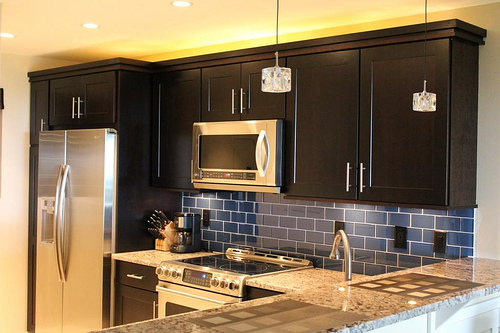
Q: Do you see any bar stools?
A: No, there are no bar stools.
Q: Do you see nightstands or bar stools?
A: No, there are no bar stools or nightstands.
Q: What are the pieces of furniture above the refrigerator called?
A: The pieces of furniture are cabinets.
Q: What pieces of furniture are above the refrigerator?
A: The pieces of furniture are cabinets.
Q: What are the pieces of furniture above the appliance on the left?
A: The pieces of furniture are cabinets.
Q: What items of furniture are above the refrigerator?
A: The pieces of furniture are cabinets.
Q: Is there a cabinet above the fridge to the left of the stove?
A: Yes, there are cabinets above the freezer.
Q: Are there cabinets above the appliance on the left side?
A: Yes, there are cabinets above the freezer.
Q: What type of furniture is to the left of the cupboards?
A: The pieces of furniture are cabinets.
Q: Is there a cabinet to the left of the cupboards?
A: Yes, there are cabinets to the left of the cupboards.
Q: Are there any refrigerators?
A: Yes, there is a refrigerator.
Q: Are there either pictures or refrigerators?
A: Yes, there is a refrigerator.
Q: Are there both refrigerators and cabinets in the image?
A: Yes, there are both a refrigerator and cabinets.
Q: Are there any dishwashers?
A: No, there are no dishwashers.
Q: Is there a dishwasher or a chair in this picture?
A: No, there are no dishwashers or chairs.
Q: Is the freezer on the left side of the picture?
A: Yes, the freezer is on the left of the image.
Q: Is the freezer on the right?
A: No, the freezer is on the left of the image.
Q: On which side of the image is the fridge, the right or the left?
A: The fridge is on the left of the image.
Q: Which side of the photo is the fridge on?
A: The fridge is on the left of the image.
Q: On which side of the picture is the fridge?
A: The fridge is on the left of the image.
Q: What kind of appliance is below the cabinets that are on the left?
A: The appliance is a refrigerator.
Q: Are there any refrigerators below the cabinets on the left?
A: Yes, there is a refrigerator below the cabinets.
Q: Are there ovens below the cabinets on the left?
A: No, there is a refrigerator below the cabinets.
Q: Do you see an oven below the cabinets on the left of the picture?
A: No, there is a refrigerator below the cabinets.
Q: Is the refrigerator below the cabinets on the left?
A: Yes, the refrigerator is below the cabinets.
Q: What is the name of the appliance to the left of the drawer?
A: The appliance is a refrigerator.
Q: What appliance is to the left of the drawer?
A: The appliance is a refrigerator.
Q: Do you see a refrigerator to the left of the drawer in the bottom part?
A: Yes, there is a refrigerator to the left of the drawer.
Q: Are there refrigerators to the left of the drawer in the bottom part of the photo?
A: Yes, there is a refrigerator to the left of the drawer.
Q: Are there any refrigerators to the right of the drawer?
A: No, the refrigerator is to the left of the drawer.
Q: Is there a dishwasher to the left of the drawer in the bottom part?
A: No, there is a refrigerator to the left of the drawer.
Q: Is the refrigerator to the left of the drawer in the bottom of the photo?
A: Yes, the refrigerator is to the left of the drawer.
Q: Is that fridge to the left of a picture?
A: No, the fridge is to the left of the drawer.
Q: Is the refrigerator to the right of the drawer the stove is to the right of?
A: No, the refrigerator is to the left of the drawer.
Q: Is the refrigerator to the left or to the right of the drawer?
A: The refrigerator is to the left of the drawer.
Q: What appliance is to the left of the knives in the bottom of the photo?
A: The appliance is a refrigerator.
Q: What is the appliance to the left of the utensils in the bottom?
A: The appliance is a refrigerator.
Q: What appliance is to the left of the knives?
A: The appliance is a refrigerator.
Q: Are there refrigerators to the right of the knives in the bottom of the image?
A: No, the refrigerator is to the left of the knives.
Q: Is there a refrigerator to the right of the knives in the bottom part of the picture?
A: No, the refrigerator is to the left of the knives.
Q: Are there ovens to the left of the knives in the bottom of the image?
A: No, there is a refrigerator to the left of the knives.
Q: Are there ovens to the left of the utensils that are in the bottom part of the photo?
A: No, there is a refrigerator to the left of the knives.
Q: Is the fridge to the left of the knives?
A: Yes, the fridge is to the left of the knives.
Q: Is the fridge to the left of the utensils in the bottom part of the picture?
A: Yes, the fridge is to the left of the knives.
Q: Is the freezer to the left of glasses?
A: No, the freezer is to the left of the knives.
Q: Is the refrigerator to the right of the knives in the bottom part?
A: No, the refrigerator is to the left of the knives.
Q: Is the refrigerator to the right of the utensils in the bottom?
A: No, the refrigerator is to the left of the knives.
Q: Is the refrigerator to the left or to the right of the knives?
A: The refrigerator is to the left of the knives.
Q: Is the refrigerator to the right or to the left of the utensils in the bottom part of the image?
A: The refrigerator is to the left of the knives.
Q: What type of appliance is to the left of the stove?
A: The appliance is a refrigerator.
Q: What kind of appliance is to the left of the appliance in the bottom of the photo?
A: The appliance is a refrigerator.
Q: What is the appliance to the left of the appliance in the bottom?
A: The appliance is a refrigerator.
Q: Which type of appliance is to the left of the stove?
A: The appliance is a refrigerator.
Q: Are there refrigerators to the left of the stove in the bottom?
A: Yes, there is a refrigerator to the left of the stove.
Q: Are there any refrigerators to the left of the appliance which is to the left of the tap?
A: Yes, there is a refrigerator to the left of the stove.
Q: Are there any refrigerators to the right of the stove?
A: No, the refrigerator is to the left of the stove.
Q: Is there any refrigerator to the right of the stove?
A: No, the refrigerator is to the left of the stove.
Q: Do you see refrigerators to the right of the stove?
A: No, the refrigerator is to the left of the stove.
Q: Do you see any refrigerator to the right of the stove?
A: No, the refrigerator is to the left of the stove.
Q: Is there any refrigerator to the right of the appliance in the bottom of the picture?
A: No, the refrigerator is to the left of the stove.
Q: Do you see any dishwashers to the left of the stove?
A: No, there is a refrigerator to the left of the stove.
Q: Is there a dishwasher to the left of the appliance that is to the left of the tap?
A: No, there is a refrigerator to the left of the stove.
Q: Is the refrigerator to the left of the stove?
A: Yes, the refrigerator is to the left of the stove.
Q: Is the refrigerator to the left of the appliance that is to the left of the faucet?
A: Yes, the refrigerator is to the left of the stove.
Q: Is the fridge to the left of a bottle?
A: No, the fridge is to the left of the stove.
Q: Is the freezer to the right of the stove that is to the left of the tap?
A: No, the freezer is to the left of the stove.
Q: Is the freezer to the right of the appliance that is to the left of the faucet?
A: No, the freezer is to the left of the stove.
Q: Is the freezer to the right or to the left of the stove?
A: The freezer is to the left of the stove.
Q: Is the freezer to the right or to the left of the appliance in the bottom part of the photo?
A: The freezer is to the left of the stove.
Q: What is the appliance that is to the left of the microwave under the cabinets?
A: The appliance is a refrigerator.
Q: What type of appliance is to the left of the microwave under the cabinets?
A: The appliance is a refrigerator.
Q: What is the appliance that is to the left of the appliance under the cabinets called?
A: The appliance is a refrigerator.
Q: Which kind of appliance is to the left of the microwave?
A: The appliance is a refrigerator.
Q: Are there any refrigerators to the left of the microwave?
A: Yes, there is a refrigerator to the left of the microwave.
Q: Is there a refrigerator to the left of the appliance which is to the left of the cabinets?
A: Yes, there is a refrigerator to the left of the microwave.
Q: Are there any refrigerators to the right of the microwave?
A: No, the refrigerator is to the left of the microwave.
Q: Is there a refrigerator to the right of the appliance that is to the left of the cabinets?
A: No, the refrigerator is to the left of the microwave.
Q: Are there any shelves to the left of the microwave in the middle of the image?
A: No, there is a refrigerator to the left of the microwave.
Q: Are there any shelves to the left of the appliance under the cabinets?
A: No, there is a refrigerator to the left of the microwave.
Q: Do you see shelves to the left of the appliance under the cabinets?
A: No, there is a refrigerator to the left of the microwave.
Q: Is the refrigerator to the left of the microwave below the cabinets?
A: Yes, the refrigerator is to the left of the microwave.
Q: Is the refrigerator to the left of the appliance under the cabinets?
A: Yes, the refrigerator is to the left of the microwave.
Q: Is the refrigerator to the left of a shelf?
A: No, the refrigerator is to the left of the microwave.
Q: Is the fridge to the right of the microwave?
A: No, the fridge is to the left of the microwave.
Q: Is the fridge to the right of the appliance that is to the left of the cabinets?
A: No, the fridge is to the left of the microwave.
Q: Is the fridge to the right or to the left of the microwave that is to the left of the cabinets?
A: The fridge is to the left of the microwave.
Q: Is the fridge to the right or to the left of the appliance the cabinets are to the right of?
A: The fridge is to the left of the microwave.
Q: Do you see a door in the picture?
A: Yes, there is a door.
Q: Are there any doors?
A: Yes, there is a door.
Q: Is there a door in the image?
A: Yes, there is a door.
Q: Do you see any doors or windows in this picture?
A: Yes, there is a door.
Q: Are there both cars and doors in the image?
A: No, there is a door but no cars.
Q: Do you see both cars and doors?
A: No, there is a door but no cars.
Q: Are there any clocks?
A: No, there are no clocks.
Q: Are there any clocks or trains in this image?
A: No, there are no clocks or trains.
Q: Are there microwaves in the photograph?
A: Yes, there is a microwave.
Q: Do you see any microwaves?
A: Yes, there is a microwave.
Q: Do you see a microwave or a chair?
A: Yes, there is a microwave.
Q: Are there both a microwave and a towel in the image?
A: No, there is a microwave but no towels.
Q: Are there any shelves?
A: No, there are no shelves.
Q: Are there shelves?
A: No, there are no shelves.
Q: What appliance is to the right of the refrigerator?
A: The appliance is a microwave.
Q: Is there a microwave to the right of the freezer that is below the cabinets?
A: Yes, there is a microwave to the right of the freezer.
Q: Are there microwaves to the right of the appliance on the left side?
A: Yes, there is a microwave to the right of the freezer.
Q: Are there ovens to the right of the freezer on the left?
A: No, there is a microwave to the right of the freezer.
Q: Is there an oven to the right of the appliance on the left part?
A: No, there is a microwave to the right of the freezer.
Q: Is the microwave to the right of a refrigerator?
A: Yes, the microwave is to the right of a refrigerator.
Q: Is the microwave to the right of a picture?
A: No, the microwave is to the right of a refrigerator.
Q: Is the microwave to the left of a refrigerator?
A: No, the microwave is to the right of a refrigerator.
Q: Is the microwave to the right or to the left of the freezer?
A: The microwave is to the right of the freezer.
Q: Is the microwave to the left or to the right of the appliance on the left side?
A: The microwave is to the right of the freezer.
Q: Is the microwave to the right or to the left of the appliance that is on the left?
A: The microwave is to the right of the freezer.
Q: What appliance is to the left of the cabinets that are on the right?
A: The appliance is a microwave.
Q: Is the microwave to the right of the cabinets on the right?
A: No, the microwave is to the left of the cabinets.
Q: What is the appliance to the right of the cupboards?
A: The appliance is a microwave.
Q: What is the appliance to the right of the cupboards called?
A: The appliance is a microwave.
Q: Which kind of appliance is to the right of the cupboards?
A: The appliance is a microwave.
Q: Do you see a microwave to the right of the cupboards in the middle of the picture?
A: Yes, there is a microwave to the right of the cupboards.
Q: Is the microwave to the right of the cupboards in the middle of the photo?
A: Yes, the microwave is to the right of the cupboards.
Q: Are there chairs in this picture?
A: No, there are no chairs.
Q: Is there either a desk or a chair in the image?
A: No, there are no chairs or desks.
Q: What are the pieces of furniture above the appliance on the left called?
A: The pieces of furniture are cabinets.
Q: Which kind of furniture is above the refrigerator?
A: The pieces of furniture are cabinets.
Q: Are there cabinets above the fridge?
A: Yes, there are cabinets above the fridge.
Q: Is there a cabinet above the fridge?
A: Yes, there are cabinets above the fridge.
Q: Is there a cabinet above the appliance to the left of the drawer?
A: Yes, there are cabinets above the fridge.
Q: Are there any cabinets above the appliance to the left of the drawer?
A: Yes, there are cabinets above the fridge.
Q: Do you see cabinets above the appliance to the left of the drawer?
A: Yes, there are cabinets above the fridge.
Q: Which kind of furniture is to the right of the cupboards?
A: The pieces of furniture are cabinets.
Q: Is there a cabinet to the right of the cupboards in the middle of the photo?
A: Yes, there are cabinets to the right of the cupboards.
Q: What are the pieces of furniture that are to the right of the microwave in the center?
A: The pieces of furniture are cabinets.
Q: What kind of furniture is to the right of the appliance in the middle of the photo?
A: The pieces of furniture are cabinets.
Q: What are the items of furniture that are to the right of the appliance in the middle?
A: The pieces of furniture are cabinets.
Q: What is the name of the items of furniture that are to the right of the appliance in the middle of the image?
A: The pieces of furniture are cabinets.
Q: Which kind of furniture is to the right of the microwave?
A: The pieces of furniture are cabinets.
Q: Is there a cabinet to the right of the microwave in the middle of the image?
A: Yes, there are cabinets to the right of the microwave.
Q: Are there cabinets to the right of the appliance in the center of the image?
A: Yes, there are cabinets to the right of the microwave.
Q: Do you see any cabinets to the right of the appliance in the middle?
A: Yes, there are cabinets to the right of the microwave.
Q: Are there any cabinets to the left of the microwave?
A: No, the cabinets are to the right of the microwave.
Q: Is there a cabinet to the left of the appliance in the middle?
A: No, the cabinets are to the right of the microwave.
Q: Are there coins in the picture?
A: No, there are no coins.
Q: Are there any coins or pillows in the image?
A: No, there are no coins or pillows.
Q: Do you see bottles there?
A: No, there are no bottles.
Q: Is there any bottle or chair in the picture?
A: No, there are no bottles or chairs.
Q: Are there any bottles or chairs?
A: No, there are no bottles or chairs.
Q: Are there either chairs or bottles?
A: No, there are no bottles or chairs.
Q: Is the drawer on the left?
A: Yes, the drawer is on the left of the image.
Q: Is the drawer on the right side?
A: No, the drawer is on the left of the image.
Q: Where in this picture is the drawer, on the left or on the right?
A: The drawer is on the left of the image.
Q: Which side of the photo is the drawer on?
A: The drawer is on the left of the image.